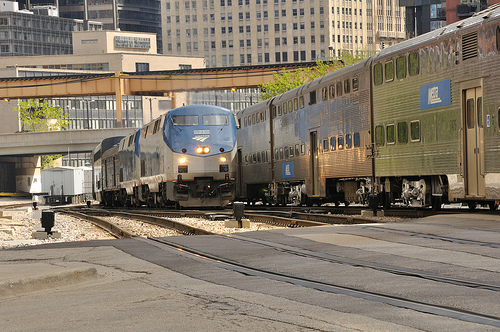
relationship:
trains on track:
[266, 18, 485, 206] [353, 198, 463, 295]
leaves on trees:
[19, 91, 74, 141] [17, 89, 75, 138]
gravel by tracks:
[68, 212, 88, 245] [90, 203, 229, 264]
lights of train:
[178, 154, 188, 166] [99, 97, 256, 235]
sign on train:
[405, 65, 474, 130] [270, 55, 485, 183]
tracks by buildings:
[10, 52, 313, 115] [15, 38, 195, 134]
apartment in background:
[161, 0, 403, 64] [27, 2, 361, 76]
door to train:
[461, 76, 483, 198] [350, 22, 477, 161]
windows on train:
[357, 105, 429, 167] [277, 55, 483, 232]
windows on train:
[202, 115, 229, 127] [77, 93, 299, 238]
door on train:
[461, 76, 483, 198] [369, 28, 485, 193]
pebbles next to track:
[66, 220, 104, 250] [89, 202, 227, 274]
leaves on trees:
[264, 66, 382, 102] [268, 46, 366, 96]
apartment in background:
[161, 0, 403, 64] [123, 8, 367, 61]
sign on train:
[417, 81, 452, 108] [350, 25, 483, 176]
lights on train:
[216, 153, 232, 163] [96, 90, 253, 221]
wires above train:
[7, 57, 128, 124] [77, 93, 299, 238]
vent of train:
[444, 33, 484, 70] [312, 31, 483, 171]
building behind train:
[20, 145, 106, 207] [88, 80, 301, 222]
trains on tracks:
[238, 4, 500, 205] [148, 232, 497, 328]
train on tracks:
[89, 88, 249, 201] [257, 193, 448, 319]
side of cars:
[260, 72, 480, 168] [296, 61, 477, 191]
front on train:
[138, 93, 285, 249] [126, 85, 327, 214]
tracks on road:
[193, 223, 399, 320] [98, 233, 311, 330]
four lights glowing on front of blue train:
[171, 148, 234, 168] [98, 134, 171, 244]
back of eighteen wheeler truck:
[27, 156, 71, 216] [61, 181, 76, 193]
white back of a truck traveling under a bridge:
[14, 171, 46, 211] [0, 134, 102, 149]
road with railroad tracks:
[1, 214, 500, 329] [206, 264, 335, 314]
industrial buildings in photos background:
[25, 55, 400, 100] [34, 101, 157, 111]